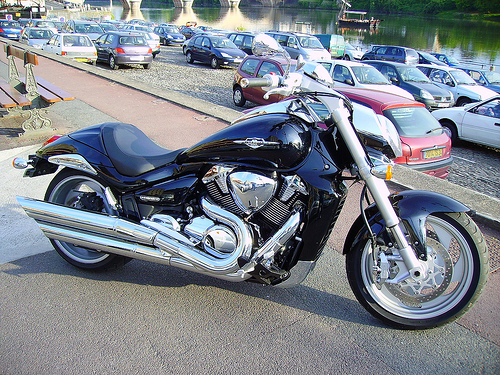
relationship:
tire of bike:
[353, 184, 481, 316] [51, 97, 463, 329]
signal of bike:
[39, 125, 70, 150] [51, 97, 463, 329]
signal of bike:
[361, 140, 404, 177] [51, 97, 463, 329]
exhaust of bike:
[12, 172, 181, 291] [51, 97, 463, 329]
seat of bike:
[103, 121, 214, 184] [51, 97, 463, 329]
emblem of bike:
[240, 133, 296, 173] [51, 97, 463, 329]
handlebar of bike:
[239, 69, 294, 100] [51, 97, 463, 329]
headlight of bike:
[368, 135, 414, 201] [51, 97, 463, 329]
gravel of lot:
[154, 42, 225, 84] [141, 31, 485, 153]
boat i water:
[333, 7, 378, 30] [378, 13, 457, 52]